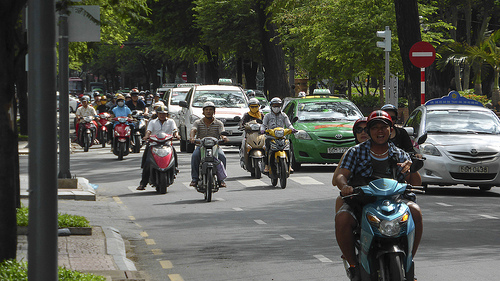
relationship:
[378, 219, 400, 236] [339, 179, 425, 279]
headlight on motorcycle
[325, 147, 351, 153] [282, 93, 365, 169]
license plate on car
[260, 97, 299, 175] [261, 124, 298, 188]
person riding motorcycle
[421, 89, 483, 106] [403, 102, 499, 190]
sign above car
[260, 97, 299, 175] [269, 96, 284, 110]
person wearing a helmet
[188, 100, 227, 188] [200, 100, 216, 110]
man wearing a helmet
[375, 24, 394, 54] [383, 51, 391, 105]
light on pole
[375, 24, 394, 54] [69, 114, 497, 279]
light beside road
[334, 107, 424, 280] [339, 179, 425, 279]
person riding a motorcycle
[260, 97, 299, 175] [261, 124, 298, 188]
person riding a motorcycle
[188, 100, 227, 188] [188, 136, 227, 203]
man riding a motorcycle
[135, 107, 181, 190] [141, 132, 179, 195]
man riding a motorcycle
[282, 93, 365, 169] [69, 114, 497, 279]
car driving on road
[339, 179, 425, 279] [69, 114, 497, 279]
motorcycle on road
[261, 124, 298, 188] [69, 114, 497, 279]
motorcycle on road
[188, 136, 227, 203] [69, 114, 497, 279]
motorcycle on road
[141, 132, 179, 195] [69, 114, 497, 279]
motorcycle on road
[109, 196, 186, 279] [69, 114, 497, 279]
line on road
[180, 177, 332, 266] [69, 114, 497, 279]
line on road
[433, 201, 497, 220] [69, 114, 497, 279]
line on road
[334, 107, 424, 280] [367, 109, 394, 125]
person wearing a helmet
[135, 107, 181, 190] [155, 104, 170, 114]
man wearing a helmet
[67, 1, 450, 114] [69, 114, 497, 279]
trees are beside of road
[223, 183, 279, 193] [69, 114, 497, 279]
shadow cast on road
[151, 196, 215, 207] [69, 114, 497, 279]
shadow cast on road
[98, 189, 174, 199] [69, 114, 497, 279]
shadow cast on road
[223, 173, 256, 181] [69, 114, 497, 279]
shadow cast on road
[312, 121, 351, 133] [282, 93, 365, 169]
graphic on car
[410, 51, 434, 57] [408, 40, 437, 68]
line on sign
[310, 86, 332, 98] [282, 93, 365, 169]
sign on top of car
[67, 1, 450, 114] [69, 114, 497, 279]
trees are next to road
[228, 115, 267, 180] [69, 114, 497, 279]
motorcycle on road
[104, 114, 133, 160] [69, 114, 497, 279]
motorcycle on road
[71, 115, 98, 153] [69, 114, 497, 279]
motorcycle on road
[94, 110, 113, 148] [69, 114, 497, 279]
motorcycle on road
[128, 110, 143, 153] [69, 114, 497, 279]
motorcycle on road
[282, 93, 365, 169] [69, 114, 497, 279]
car on road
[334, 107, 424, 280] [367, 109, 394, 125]
person wearing helmet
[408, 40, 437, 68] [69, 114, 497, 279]
sign beside of road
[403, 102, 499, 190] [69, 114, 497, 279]
car driving on road